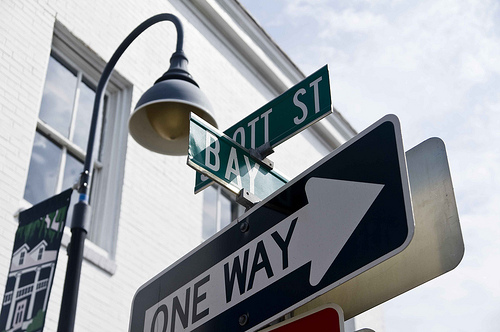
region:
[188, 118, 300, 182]
street signs in different directions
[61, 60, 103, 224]
window on the building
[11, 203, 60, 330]
printed sign on the post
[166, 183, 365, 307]
arrow is white background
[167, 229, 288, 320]
letters are in black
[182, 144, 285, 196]
word bay is on sign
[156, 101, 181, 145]
light is yellow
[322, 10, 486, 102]
clouds in the sky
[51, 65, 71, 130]
pane of the window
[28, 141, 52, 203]
pane of the window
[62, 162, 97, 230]
pane of the window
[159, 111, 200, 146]
light in the globe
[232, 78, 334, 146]
street sign on pole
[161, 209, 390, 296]
street sign on pole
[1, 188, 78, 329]
flag on the pole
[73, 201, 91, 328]
black pole on the street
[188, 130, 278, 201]
street sign on pole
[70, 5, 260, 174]
A metal street lamp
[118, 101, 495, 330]
A black and white one way sign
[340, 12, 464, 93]
A partly cloudy sky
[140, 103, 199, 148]
A light bulb in a street lamp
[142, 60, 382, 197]
Green and white street signs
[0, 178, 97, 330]
A decorative banner on a light pole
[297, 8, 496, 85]
White puffy clouds in a blue sky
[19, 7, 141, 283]
A window on a brick building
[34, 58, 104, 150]
Part of a glass window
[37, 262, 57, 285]
THAT IS A WINDOW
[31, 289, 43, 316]
THAT IS A WINDOW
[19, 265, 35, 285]
THAT IS A WINDOW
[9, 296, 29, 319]
THAT IS A WINDOW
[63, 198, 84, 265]
THIS IS A POLE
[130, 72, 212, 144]
THAT IS A STREET LIGHT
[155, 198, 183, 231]
THE WALL OF A BULDING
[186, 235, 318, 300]
a traffic sign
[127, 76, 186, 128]
a street light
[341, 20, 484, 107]
the clouds in the sky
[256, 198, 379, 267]
a black and white sign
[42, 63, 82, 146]
window on the building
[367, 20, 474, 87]
the cloud is white in the sky